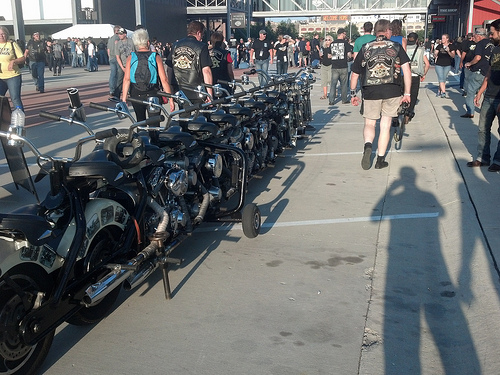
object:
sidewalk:
[224, 116, 500, 375]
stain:
[440, 290, 455, 297]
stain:
[346, 255, 363, 264]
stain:
[267, 257, 281, 268]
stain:
[327, 183, 337, 186]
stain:
[280, 330, 292, 336]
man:
[166, 20, 214, 119]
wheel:
[241, 204, 261, 238]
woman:
[119, 29, 176, 127]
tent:
[51, 23, 135, 39]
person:
[390, 20, 406, 51]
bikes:
[0, 60, 320, 375]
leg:
[381, 311, 422, 374]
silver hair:
[132, 30, 150, 46]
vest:
[129, 51, 157, 91]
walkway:
[185, 0, 425, 13]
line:
[326, 212, 439, 224]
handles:
[204, 98, 227, 107]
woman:
[0, 26, 26, 112]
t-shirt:
[0, 43, 23, 80]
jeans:
[0, 75, 23, 110]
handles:
[88, 102, 115, 112]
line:
[365, 238, 379, 323]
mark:
[305, 255, 366, 270]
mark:
[264, 260, 283, 267]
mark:
[326, 183, 336, 186]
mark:
[440, 289, 454, 298]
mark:
[279, 330, 291, 337]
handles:
[39, 111, 68, 121]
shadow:
[369, 165, 465, 374]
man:
[204, 32, 235, 98]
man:
[249, 29, 273, 85]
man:
[329, 28, 352, 106]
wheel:
[0, 266, 55, 375]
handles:
[80, 128, 116, 140]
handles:
[134, 115, 164, 125]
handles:
[175, 104, 202, 113]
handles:
[158, 92, 176, 98]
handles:
[232, 91, 247, 98]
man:
[350, 20, 413, 169]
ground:
[4, 66, 498, 370]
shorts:
[363, 94, 404, 120]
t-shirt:
[435, 43, 454, 65]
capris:
[434, 65, 451, 83]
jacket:
[165, 35, 213, 99]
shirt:
[349, 37, 412, 100]